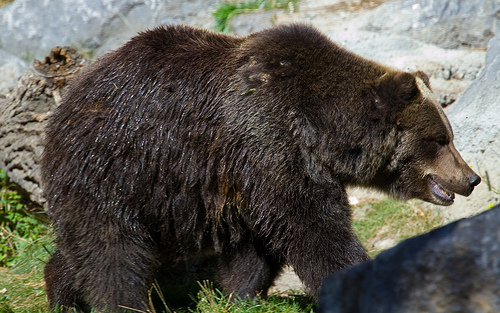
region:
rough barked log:
[1, 38, 73, 205]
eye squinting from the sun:
[415, 122, 462, 157]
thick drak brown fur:
[39, 21, 374, 305]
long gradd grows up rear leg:
[121, 276, 183, 311]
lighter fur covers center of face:
[412, 63, 480, 181]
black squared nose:
[457, 158, 484, 197]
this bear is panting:
[418, 128, 483, 212]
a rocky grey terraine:
[0, 0, 499, 307]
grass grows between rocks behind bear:
[206, 0, 303, 35]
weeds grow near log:
[2, 176, 42, 276]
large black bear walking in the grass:
[23, 21, 480, 311]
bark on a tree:
[1, 45, 90, 213]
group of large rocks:
[5, 0, 494, 213]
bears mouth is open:
[383, 71, 480, 204]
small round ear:
[382, 64, 417, 100]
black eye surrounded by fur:
[430, 130, 451, 147]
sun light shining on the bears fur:
[120, 84, 269, 196]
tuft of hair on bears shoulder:
[273, 14, 330, 55]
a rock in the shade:
[315, 205, 491, 310]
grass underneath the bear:
[129, 268, 312, 312]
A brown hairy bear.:
[38, 27, 478, 312]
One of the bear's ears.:
[375, 68, 418, 112]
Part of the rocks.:
[362, 13, 477, 58]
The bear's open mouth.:
[422, 170, 469, 210]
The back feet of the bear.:
[43, 242, 164, 312]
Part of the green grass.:
[6, 260, 39, 300]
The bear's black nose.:
[467, 172, 481, 190]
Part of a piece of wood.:
[7, 95, 41, 149]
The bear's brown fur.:
[124, 111, 240, 196]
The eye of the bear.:
[431, 131, 453, 150]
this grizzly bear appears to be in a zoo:
[35, 18, 480, 311]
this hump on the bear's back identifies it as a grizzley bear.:
[231, 19, 351, 73]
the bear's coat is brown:
[33, 23, 484, 308]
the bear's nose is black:
[463, 171, 483, 190]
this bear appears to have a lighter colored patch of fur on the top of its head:
[408, 65, 465, 160]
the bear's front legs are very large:
[218, 153, 374, 310]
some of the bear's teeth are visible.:
[423, 172, 458, 207]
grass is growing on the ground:
[186, 273, 322, 309]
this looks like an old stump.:
[2, 38, 94, 212]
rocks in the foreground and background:
[309, 21, 499, 311]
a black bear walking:
[29, 17, 496, 309]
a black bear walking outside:
[29, 30, 457, 280]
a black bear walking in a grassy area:
[12, 8, 458, 312]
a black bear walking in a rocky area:
[22, 27, 428, 311]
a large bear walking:
[22, 13, 494, 283]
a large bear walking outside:
[19, 27, 418, 307]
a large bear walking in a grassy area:
[10, 11, 410, 309]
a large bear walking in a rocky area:
[26, 20, 494, 310]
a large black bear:
[35, 15, 442, 311]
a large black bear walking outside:
[17, 31, 497, 295]